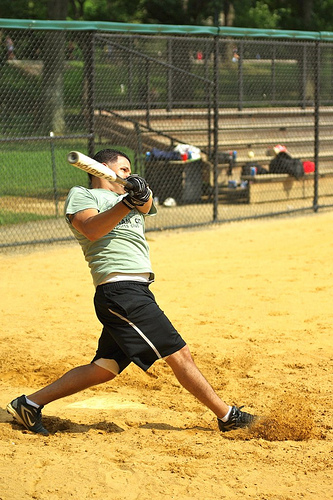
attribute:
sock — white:
[218, 402, 238, 420]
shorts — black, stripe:
[90, 280, 186, 374]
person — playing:
[2, 146, 270, 441]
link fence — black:
[1, 21, 331, 254]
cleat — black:
[213, 388, 265, 436]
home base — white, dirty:
[72, 392, 135, 425]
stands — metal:
[95, 106, 331, 202]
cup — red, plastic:
[178, 146, 189, 164]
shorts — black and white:
[80, 278, 188, 371]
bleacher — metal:
[86, 90, 332, 213]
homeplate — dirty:
[68, 393, 145, 411]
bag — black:
[268, 149, 305, 184]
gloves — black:
[122, 181, 156, 210]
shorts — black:
[84, 285, 183, 360]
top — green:
[122, 10, 244, 49]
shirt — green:
[78, 188, 163, 298]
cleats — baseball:
[209, 404, 276, 431]